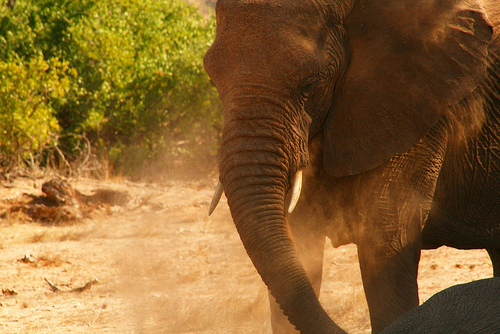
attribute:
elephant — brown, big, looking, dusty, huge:
[203, 1, 499, 331]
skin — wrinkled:
[311, 119, 495, 241]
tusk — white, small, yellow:
[287, 169, 304, 215]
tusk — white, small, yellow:
[209, 180, 222, 218]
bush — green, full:
[2, 2, 225, 182]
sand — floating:
[119, 112, 219, 229]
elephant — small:
[372, 275, 499, 332]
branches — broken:
[8, 127, 117, 188]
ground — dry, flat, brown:
[9, 166, 490, 326]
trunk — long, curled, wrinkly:
[219, 93, 339, 331]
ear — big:
[326, 2, 492, 176]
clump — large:
[22, 250, 92, 298]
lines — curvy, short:
[472, 49, 497, 180]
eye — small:
[305, 83, 316, 91]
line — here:
[225, 83, 290, 95]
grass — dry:
[13, 211, 125, 244]